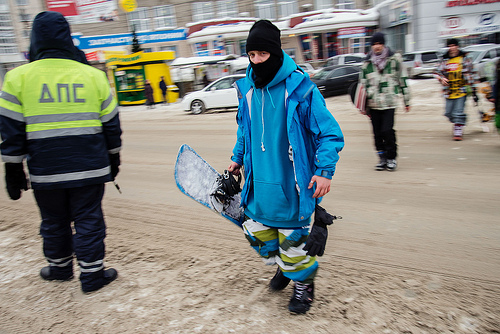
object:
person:
[223, 17, 344, 314]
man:
[1, 10, 121, 297]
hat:
[26, 9, 85, 63]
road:
[7, 119, 496, 296]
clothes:
[0, 47, 125, 291]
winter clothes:
[229, 53, 347, 229]